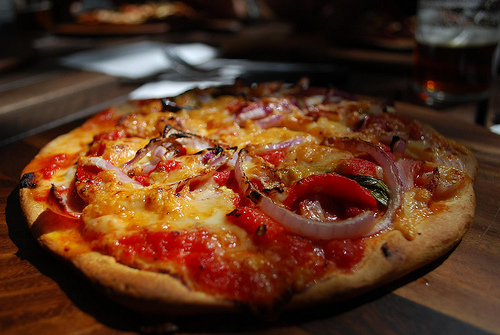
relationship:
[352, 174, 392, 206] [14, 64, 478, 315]
leaf on top pizza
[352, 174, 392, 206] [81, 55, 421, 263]
leaf on top pizza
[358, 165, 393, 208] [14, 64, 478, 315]
leaf on top pizza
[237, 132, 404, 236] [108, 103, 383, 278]
onion on top pizza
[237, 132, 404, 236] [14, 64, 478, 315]
onion on top pizza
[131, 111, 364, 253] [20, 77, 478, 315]
big onion on top pizza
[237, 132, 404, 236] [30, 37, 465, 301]
onion on top pizza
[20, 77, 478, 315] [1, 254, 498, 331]
pizza on wood surface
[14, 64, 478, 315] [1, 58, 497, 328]
pizza on surface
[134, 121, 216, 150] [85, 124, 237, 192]
burnt edge of onion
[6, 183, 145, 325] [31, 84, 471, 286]
shadow on side pizza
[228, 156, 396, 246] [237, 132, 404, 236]
pepperoni sticking up onion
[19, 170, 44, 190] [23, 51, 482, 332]
spot on pizza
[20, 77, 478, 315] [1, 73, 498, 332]
pizza on table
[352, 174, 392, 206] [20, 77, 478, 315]
leaf on pizza